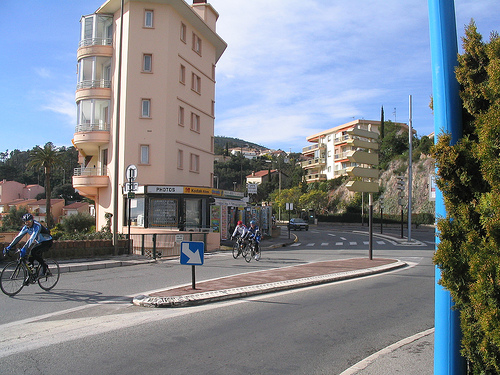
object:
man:
[243, 220, 261, 258]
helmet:
[250, 221, 256, 225]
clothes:
[244, 226, 261, 251]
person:
[232, 220, 248, 237]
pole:
[430, 0, 465, 373]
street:
[0, 227, 436, 370]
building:
[73, 0, 228, 253]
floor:
[75, 142, 212, 187]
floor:
[73, 96, 212, 153]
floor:
[77, 13, 216, 80]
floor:
[76, 59, 215, 116]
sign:
[180, 242, 204, 265]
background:
[181, 243, 203, 265]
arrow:
[182, 243, 201, 264]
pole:
[408, 95, 412, 240]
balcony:
[77, 13, 114, 61]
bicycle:
[0, 248, 60, 296]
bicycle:
[233, 237, 246, 259]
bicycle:
[245, 238, 262, 263]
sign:
[147, 186, 183, 193]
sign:
[184, 187, 212, 195]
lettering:
[156, 187, 175, 191]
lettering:
[191, 189, 209, 193]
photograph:
[0, 0, 500, 368]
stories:
[73, 96, 111, 142]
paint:
[0, 258, 417, 356]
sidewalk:
[133, 257, 407, 308]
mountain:
[214, 136, 298, 188]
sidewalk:
[340, 329, 433, 375]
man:
[3, 213, 53, 274]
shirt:
[8, 221, 52, 250]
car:
[287, 218, 309, 231]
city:
[0, 0, 498, 371]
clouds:
[211, 1, 421, 137]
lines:
[0, 295, 133, 329]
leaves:
[25, 143, 63, 171]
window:
[178, 105, 184, 127]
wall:
[129, 29, 167, 52]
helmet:
[23, 213, 33, 220]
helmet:
[238, 221, 243, 225]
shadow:
[9, 289, 132, 304]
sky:
[0, 0, 493, 161]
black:
[32, 241, 53, 252]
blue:
[8, 222, 52, 256]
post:
[129, 169, 131, 253]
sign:
[126, 164, 138, 180]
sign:
[125, 183, 138, 191]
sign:
[128, 193, 135, 198]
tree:
[431, 22, 497, 372]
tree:
[26, 142, 69, 232]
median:
[133, 258, 407, 309]